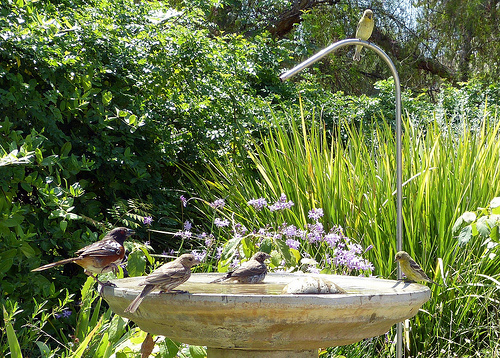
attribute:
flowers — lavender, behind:
[167, 196, 408, 284]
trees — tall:
[189, 0, 493, 145]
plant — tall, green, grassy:
[424, 228, 497, 353]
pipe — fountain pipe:
[315, 39, 466, 253]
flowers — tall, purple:
[170, 190, 495, 279]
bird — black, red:
[31, 225, 136, 288]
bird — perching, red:
[113, 247, 203, 314]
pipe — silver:
[250, 32, 449, 353]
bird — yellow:
[345, 5, 384, 60]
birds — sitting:
[233, 247, 277, 287]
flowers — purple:
[171, 181, 374, 271]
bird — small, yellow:
[128, 252, 199, 320]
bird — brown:
[24, 219, 145, 272]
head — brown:
[104, 217, 138, 243]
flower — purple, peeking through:
[331, 245, 368, 272]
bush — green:
[2, 1, 223, 327]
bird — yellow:
[352, 9, 377, 59]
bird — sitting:
[123, 248, 205, 324]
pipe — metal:
[393, 110, 405, 235]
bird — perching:
[124, 249, 204, 317]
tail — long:
[121, 284, 151, 316]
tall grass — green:
[274, 112, 381, 204]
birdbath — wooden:
[99, 266, 435, 356]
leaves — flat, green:
[391, 85, 472, 202]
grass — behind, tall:
[264, 94, 494, 279]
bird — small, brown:
[212, 249, 279, 290]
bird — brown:
[130, 256, 192, 318]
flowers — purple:
[185, 168, 400, 268]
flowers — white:
[237, 193, 373, 271]